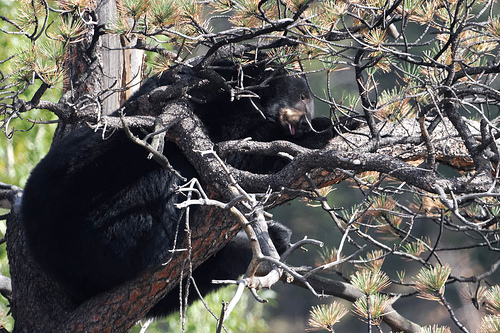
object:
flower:
[308, 301, 350, 331]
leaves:
[14, 0, 46, 28]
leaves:
[362, 247, 386, 269]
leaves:
[413, 263, 450, 298]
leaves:
[375, 85, 409, 118]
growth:
[354, 282, 393, 323]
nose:
[300, 118, 309, 126]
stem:
[216, 137, 319, 160]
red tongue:
[289, 125, 296, 134]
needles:
[373, 281, 393, 291]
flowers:
[316, 245, 348, 271]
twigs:
[433, 0, 497, 97]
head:
[235, 62, 312, 137]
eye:
[301, 93, 305, 101]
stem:
[65, 10, 139, 112]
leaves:
[331, 90, 361, 106]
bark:
[0, 47, 487, 333]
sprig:
[300, 235, 323, 253]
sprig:
[424, 206, 445, 261]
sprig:
[305, 280, 332, 299]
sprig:
[355, 223, 412, 248]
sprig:
[256, 184, 272, 206]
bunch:
[365, 195, 396, 215]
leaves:
[408, 192, 438, 212]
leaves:
[263, 43, 303, 70]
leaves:
[359, 30, 393, 71]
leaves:
[348, 193, 395, 228]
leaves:
[148, 53, 170, 77]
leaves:
[375, 88, 405, 117]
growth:
[0, 1, 472, 329]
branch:
[3, 113, 499, 325]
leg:
[307, 116, 355, 147]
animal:
[20, 44, 366, 320]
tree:
[0, 1, 498, 333]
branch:
[64, 115, 490, 333]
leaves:
[27, 53, 65, 89]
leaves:
[347, 271, 392, 294]